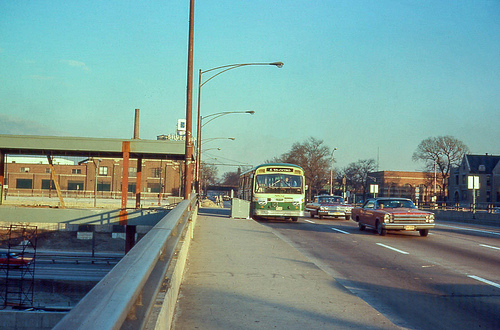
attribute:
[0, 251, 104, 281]
road — below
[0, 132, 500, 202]
buildings — red, bricked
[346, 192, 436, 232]
car — red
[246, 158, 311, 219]
bus — green, white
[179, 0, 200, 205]
utility pole — tall, brown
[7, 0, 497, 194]
sky — clear, blue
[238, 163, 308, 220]
bus — old, green, yellow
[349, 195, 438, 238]
car — red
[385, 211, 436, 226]
bumper — chrome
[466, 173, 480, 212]
street sign — metal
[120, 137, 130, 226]
beam — metal, rusty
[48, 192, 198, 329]
railing — metal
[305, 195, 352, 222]
car — red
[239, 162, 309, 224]
bus — green, yellow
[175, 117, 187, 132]
sign — blue, white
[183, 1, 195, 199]
pole — rusty, metal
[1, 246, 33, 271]
car — red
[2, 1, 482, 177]
sky — blue, clear